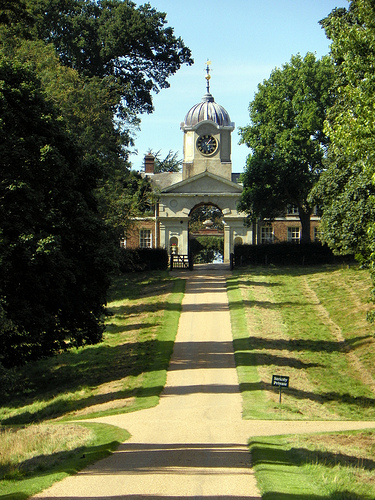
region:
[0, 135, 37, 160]
clock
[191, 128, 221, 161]
black and white clock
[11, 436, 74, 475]
short brown and green grass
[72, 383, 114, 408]
short brown and green grass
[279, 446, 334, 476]
short brown and green grass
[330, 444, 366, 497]
short brown and green grass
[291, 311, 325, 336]
short brown and green grass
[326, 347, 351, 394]
short brown and green grass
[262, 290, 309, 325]
short brown and green grass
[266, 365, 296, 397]
black and white sign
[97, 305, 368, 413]
shadows on the ground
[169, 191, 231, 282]
the entrance is open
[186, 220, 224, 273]
water in the background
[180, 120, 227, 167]
the clock face is black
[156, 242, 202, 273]
the gate is open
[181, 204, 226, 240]
a fountain in the distance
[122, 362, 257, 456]
the sun is out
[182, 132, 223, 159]
the hands on the clock are gold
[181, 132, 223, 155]
the numbers are roman numerals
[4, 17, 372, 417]
trees are on both sides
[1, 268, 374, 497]
THE PATH LEADS TO A BUILDING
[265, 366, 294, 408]
THE SIGN IS BLACK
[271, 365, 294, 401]
THE SIGN SAYS PRIVATE PROPERTY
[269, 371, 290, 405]
THE SIGN IS SMALL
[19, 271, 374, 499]
THE PATH IS BEIGE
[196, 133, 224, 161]
THIS IS A CLOCK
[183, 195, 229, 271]
THIS IS AN ARCHWAY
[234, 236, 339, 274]
THIS IS A SHRUB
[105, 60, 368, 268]
THE BUILDING IS BRICK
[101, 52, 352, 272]
THE BUILDING HAS MANY WINDOWS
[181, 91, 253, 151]
a dome-shaped roof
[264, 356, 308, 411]
a small black sign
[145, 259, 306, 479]
shadows on the ground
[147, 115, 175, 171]
the sky is clear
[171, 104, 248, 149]
the roof is gray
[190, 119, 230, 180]
a clock face on the wall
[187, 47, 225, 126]
a cross on the roof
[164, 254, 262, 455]
the long walk way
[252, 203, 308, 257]
windows on the wall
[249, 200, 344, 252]
a brown bricked wall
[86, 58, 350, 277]
a building with a clock tower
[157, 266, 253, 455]
a pathway leads to the clock tower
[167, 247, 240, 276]
the gates are open to the clock tower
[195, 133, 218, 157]
the clock face is black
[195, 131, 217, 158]
the clock hands and roman numerals are gold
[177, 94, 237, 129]
a cupola is above the clock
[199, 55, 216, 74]
a weather vane is on top of the tower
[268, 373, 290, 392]
a sign is by the pathway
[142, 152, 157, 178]
a red brick chimney is on the building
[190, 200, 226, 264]
a fountain is through the clock tower arch